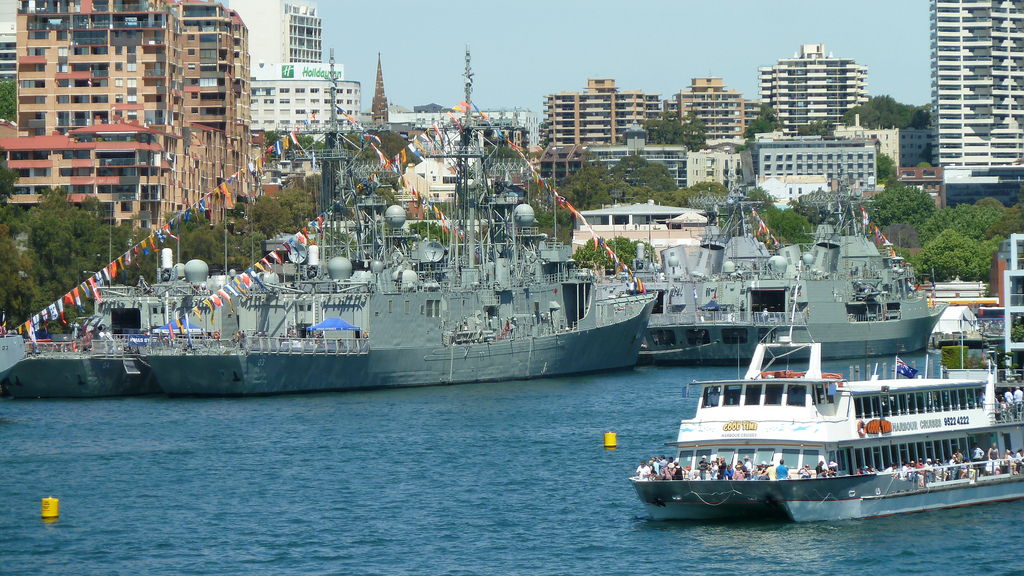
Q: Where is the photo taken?
A: Harbor.